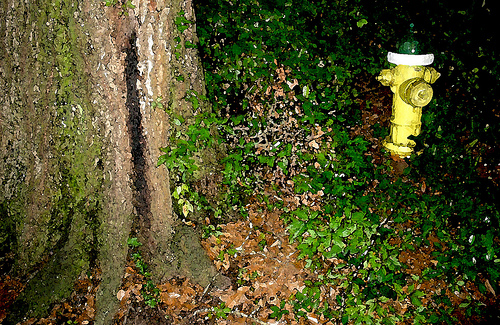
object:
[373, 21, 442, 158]
hydrant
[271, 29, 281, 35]
leaves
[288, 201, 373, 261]
bush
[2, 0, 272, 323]
tree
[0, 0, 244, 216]
trunk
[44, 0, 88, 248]
moss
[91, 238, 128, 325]
roots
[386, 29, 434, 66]
top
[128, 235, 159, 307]
vine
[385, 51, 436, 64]
stripe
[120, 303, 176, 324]
dirt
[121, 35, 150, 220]
stripe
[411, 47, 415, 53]
reflection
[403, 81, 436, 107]
spigot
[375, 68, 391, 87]
spigot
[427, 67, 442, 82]
spigot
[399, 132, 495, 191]
shadows